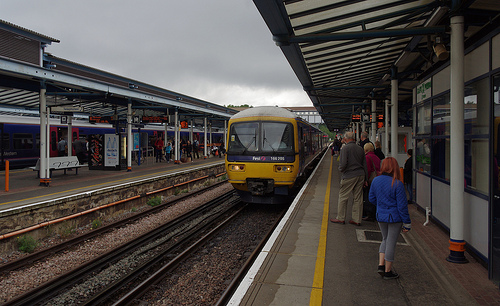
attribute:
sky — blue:
[106, 12, 246, 84]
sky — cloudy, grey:
[66, 4, 263, 66]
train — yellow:
[222, 107, 324, 207]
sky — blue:
[15, 9, 312, 103]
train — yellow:
[218, 103, 331, 210]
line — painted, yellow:
[306, 189, 344, 304]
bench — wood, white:
[28, 153, 91, 180]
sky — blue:
[139, 16, 296, 107]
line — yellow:
[306, 153, 333, 304]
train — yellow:
[217, 96, 304, 211]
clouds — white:
[131, 17, 263, 84]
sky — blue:
[36, 0, 313, 117]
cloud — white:
[1, 2, 305, 94]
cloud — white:
[147, 78, 318, 112]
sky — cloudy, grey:
[10, 1, 293, 105]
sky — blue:
[85, 6, 202, 97]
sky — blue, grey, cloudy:
[1, 1, 321, 109]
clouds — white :
[4, 1, 308, 88]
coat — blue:
[369, 174, 411, 224]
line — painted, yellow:
[312, 132, 329, 301]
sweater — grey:
[332, 140, 367, 176]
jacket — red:
[362, 150, 380, 174]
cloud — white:
[185, 77, 320, 109]